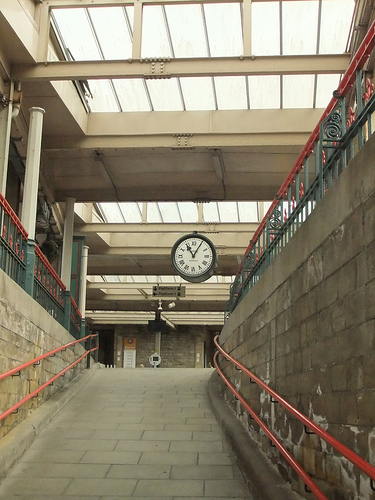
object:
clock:
[169, 232, 218, 283]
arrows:
[192, 236, 206, 258]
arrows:
[186, 241, 194, 258]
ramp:
[0, 364, 265, 499]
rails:
[211, 334, 373, 499]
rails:
[0, 332, 102, 420]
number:
[191, 238, 197, 249]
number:
[201, 247, 208, 254]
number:
[203, 252, 210, 260]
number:
[201, 260, 208, 265]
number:
[189, 264, 195, 275]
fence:
[0, 199, 96, 352]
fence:
[227, 22, 374, 315]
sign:
[122, 350, 136, 366]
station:
[0, 0, 374, 498]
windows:
[279, 0, 318, 58]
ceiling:
[0, 0, 374, 328]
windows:
[237, 200, 258, 225]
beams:
[13, 54, 372, 84]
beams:
[71, 221, 269, 233]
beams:
[83, 279, 234, 291]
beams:
[84, 310, 226, 320]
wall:
[112, 325, 207, 366]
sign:
[152, 285, 186, 295]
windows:
[117, 272, 133, 286]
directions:
[152, 283, 158, 298]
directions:
[176, 283, 184, 298]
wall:
[216, 132, 375, 499]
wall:
[0, 268, 87, 440]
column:
[19, 105, 47, 249]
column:
[59, 196, 78, 296]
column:
[77, 245, 90, 321]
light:
[95, 155, 118, 197]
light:
[209, 152, 225, 184]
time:
[183, 237, 206, 258]